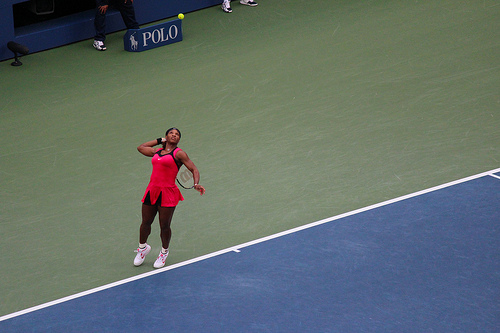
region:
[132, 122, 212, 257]
woman wearing red outfit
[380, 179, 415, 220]
green white and blue tennis court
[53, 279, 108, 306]
green white and blue tennis court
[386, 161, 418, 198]
green white and blue tennis court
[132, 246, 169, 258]
pink and white socks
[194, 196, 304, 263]
white line on court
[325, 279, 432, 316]
court is dark blue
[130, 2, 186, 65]
blue and white sign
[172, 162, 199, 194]
black and red racket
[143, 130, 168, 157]
Serena has black wristband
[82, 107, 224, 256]
woman on the court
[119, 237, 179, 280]
shoes of the woman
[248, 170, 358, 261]
line on the ground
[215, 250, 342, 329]
blue court under the lady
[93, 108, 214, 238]
lady looking up at ball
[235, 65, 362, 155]
green court next to lady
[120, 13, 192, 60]
word on the object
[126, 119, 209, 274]
woman swinging tennis racket on court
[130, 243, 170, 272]
pair of white sneakers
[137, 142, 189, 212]
red tennis outfit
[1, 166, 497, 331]
white line on tennis court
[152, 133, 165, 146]
black wrist band on tennis player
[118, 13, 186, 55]
blue sponsor block on side of tennis court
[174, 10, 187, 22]
green tennis ball in mid air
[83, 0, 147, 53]
person standing against wall surrounding tennis court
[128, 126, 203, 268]
a female tennis player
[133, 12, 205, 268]
a tennis player swinging for ball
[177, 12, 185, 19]
a yellow tennis ball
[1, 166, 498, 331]
a blue marked tennis court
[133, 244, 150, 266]
a white and pink tennis shoe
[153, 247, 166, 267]
a white and pink tennis shoe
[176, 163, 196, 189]
a black tennis racket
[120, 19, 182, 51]
a POLO stadium advertisement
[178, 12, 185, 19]
a yellow tennis ball on ground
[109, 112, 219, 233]
woman on the court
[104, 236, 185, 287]
shoes on the woman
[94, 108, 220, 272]
tennis player on court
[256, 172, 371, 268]
white line on ground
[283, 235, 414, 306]
blue court on ground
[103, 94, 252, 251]
person wearing the color purple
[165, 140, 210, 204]
racket in lady's hand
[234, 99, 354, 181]
green court behind lady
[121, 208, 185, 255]
legs of the lady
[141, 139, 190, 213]
player wearing a red dress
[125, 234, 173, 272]
playing wearing white shoes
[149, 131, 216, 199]
player swinging tennis racket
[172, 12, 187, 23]
green tennis ball in the air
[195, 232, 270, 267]
white line on the court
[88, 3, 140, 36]
man wearing black pants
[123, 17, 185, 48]
blue sign on the ground